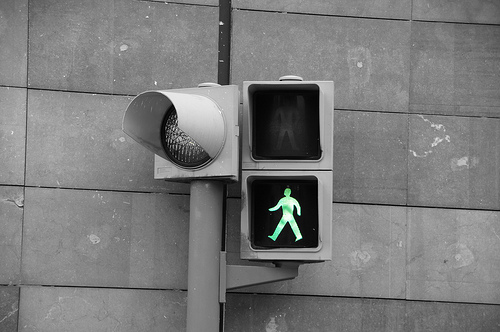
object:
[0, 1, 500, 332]
wall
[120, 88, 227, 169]
light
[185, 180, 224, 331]
pole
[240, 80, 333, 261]
signal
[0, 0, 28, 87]
block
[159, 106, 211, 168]
lens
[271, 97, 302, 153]
man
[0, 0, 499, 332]
building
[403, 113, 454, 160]
stain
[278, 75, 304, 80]
knob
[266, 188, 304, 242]
person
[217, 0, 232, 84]
line